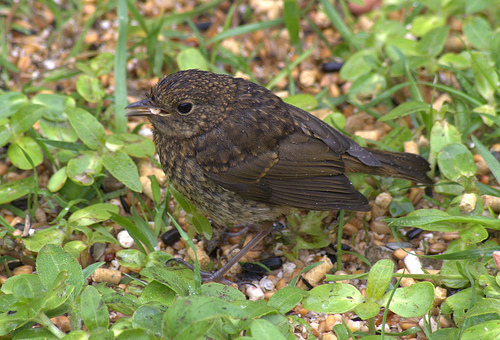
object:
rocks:
[10, 21, 84, 108]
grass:
[345, 23, 490, 87]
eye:
[178, 95, 194, 116]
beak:
[123, 87, 160, 124]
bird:
[123, 64, 433, 239]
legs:
[210, 223, 273, 275]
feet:
[160, 257, 236, 289]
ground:
[23, 22, 139, 328]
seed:
[237, 252, 339, 300]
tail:
[343, 147, 437, 185]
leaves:
[69, 101, 131, 179]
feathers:
[177, 144, 261, 225]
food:
[240, 251, 433, 305]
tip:
[354, 42, 409, 113]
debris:
[21, 17, 98, 76]